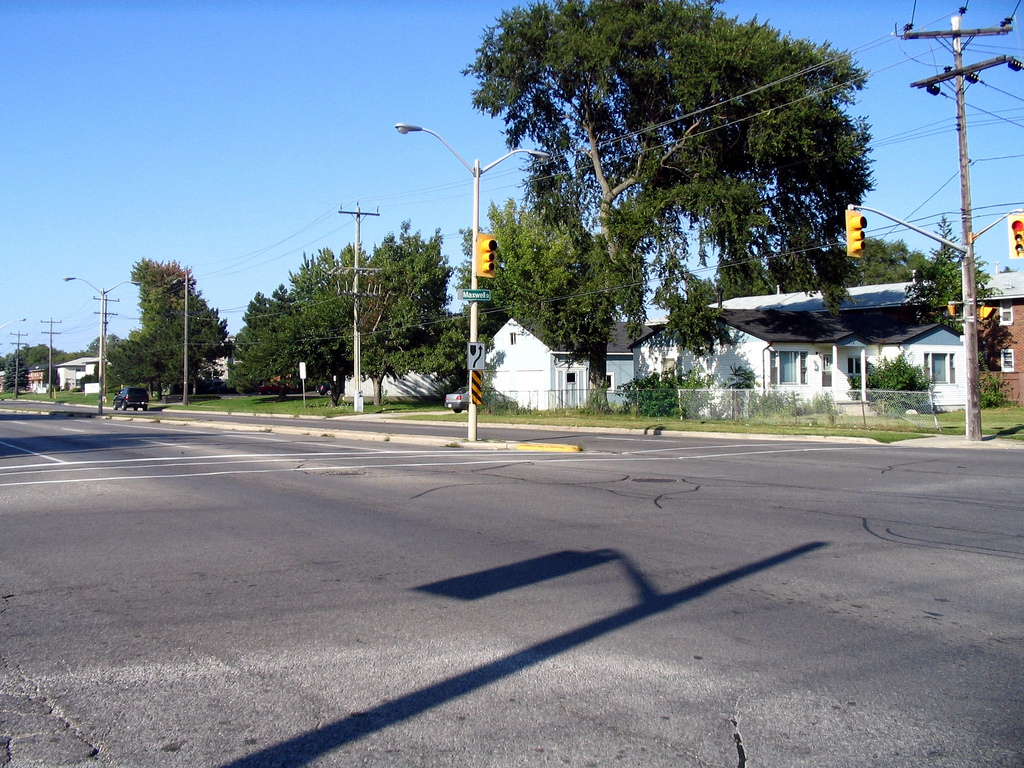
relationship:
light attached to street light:
[396, 126, 410, 135] [395, 122, 551, 439]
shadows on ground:
[1, 387, 1021, 766] [0, 388, 1023, 766]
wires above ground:
[0, 1, 1023, 347] [0, 414, 1022, 767]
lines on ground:
[0, 418, 876, 487] [0, 414, 1022, 767]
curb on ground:
[0, 396, 1023, 458] [0, 414, 1022, 767]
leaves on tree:
[460, 0, 877, 362] [456, 0, 876, 413]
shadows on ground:
[1, 387, 1021, 766] [0, 414, 1022, 767]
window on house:
[846, 355, 862, 377] [625, 302, 967, 417]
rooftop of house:
[628, 302, 990, 356] [625, 302, 967, 417]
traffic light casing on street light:
[473, 231, 497, 277] [395, 122, 551, 439]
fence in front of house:
[548, 384, 951, 431] [625, 302, 967, 417]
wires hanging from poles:
[0, 1, 1023, 347] [0, 0, 1023, 443]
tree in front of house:
[456, 0, 876, 413] [625, 302, 967, 417]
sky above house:
[0, 0, 1021, 355] [625, 302, 967, 417]